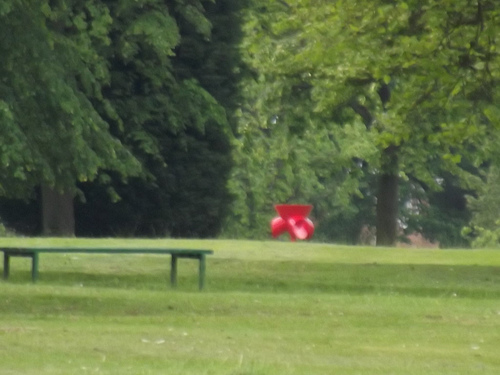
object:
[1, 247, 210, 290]
bench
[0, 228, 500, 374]
grass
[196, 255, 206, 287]
legs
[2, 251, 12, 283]
legs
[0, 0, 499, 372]
field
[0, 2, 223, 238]
tree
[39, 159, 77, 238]
trunk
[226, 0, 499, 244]
tree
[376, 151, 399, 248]
trunk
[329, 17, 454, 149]
leaves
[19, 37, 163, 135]
leaves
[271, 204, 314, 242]
object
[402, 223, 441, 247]
building